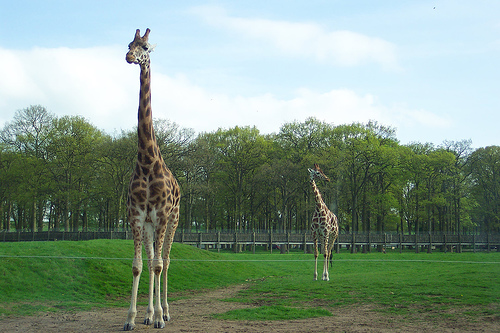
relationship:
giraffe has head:
[118, 20, 185, 330] [124, 25, 154, 65]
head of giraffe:
[124, 25, 154, 65] [118, 20, 185, 330]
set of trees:
[367, 180, 453, 250] [341, 164, 477, 246]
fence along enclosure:
[6, 222, 483, 264] [2, 237, 482, 329]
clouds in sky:
[2, 47, 281, 141] [0, 1, 479, 170]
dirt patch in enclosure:
[167, 275, 260, 329] [2, 237, 482, 329]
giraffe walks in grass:
[295, 157, 342, 283] [229, 254, 482, 308]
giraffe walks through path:
[118, 20, 185, 330] [72, 279, 269, 330]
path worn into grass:
[72, 279, 269, 330] [2, 237, 483, 330]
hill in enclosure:
[0, 238, 298, 312] [2, 237, 482, 329]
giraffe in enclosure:
[118, 20, 185, 330] [2, 237, 482, 329]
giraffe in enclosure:
[295, 157, 342, 283] [2, 237, 482, 329]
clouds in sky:
[13, 41, 383, 130] [3, 6, 483, 146]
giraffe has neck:
[295, 157, 348, 292] [309, 173, 330, 218]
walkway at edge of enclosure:
[194, 223, 498, 251] [4, 212, 498, 329]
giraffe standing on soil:
[118, 20, 185, 330] [3, 280, 493, 330]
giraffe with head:
[295, 157, 342, 283] [306, 163, 332, 184]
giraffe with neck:
[295, 157, 342, 283] [310, 177, 324, 204]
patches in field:
[0, 283, 497, 331] [2, 239, 496, 330]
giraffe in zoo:
[295, 157, 342, 283] [2, 227, 497, 331]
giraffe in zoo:
[118, 20, 185, 330] [2, 227, 497, 331]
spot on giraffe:
[148, 159, 164, 179] [118, 20, 185, 330]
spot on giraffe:
[145, 172, 155, 182] [118, 20, 185, 330]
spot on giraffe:
[138, 167, 151, 177] [118, 20, 185, 330]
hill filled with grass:
[0, 234, 236, 331] [0, 237, 235, 308]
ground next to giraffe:
[199, 252, 495, 331] [303, 167, 341, 285]